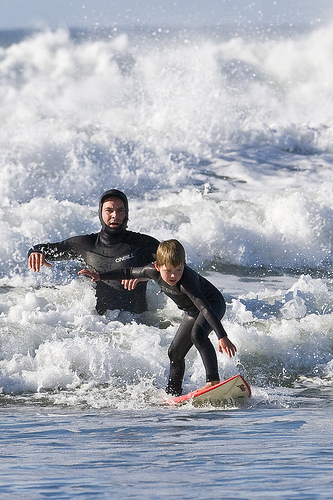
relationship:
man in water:
[28, 189, 169, 316] [1, 30, 333, 499]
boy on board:
[79, 239, 238, 397] [166, 372, 253, 407]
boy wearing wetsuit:
[79, 239, 238, 397] [98, 263, 228, 398]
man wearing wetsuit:
[28, 189, 169, 316] [29, 189, 169, 312]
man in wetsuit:
[28, 189, 169, 316] [29, 189, 169, 312]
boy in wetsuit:
[79, 239, 238, 397] [98, 263, 228, 398]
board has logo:
[166, 372, 253, 407] [237, 382, 247, 396]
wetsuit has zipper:
[98, 263, 228, 398] [156, 287, 164, 297]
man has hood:
[28, 189, 169, 316] [96, 188, 134, 235]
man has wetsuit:
[28, 189, 169, 316] [29, 189, 169, 312]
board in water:
[166, 372, 253, 407] [1, 30, 333, 499]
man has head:
[28, 189, 169, 316] [99, 189, 132, 234]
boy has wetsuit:
[79, 239, 238, 397] [98, 263, 228, 398]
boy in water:
[79, 239, 238, 397] [1, 30, 333, 499]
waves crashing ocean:
[143, 180, 322, 259] [3, 29, 322, 487]